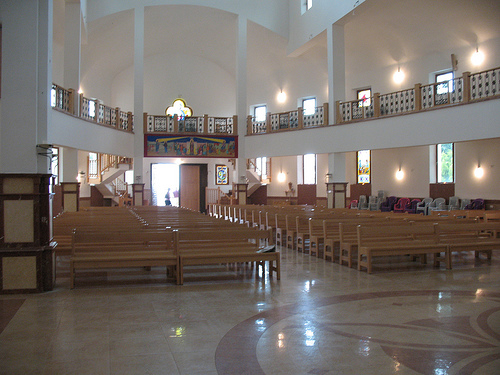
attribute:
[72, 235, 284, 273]
pew — wooden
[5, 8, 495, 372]
church — empty, large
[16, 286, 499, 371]
floor — tiled, shiny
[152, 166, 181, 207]
door — open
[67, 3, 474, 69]
ceiling — high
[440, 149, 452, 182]
glass — stained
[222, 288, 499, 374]
design — large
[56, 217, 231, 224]
pew — wooden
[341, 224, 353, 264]
pew — wooden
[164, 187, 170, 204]
person — standing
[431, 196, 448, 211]
chair — plastic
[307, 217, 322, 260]
pew — wooden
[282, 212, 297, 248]
pew — wooden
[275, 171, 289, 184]
light — on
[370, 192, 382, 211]
chair — stacked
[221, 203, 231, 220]
pew — wooden